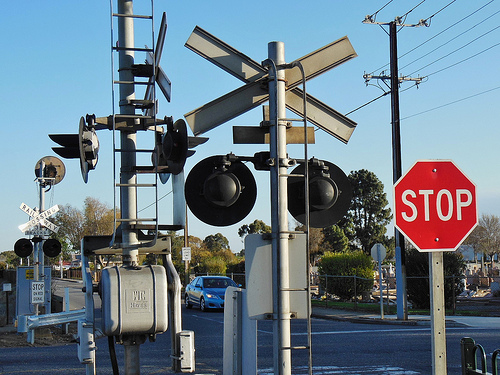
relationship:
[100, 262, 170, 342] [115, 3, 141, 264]
machine operating bar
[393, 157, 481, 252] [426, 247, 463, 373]
sign on a metal pole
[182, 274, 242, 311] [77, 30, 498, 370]
car on a crossing